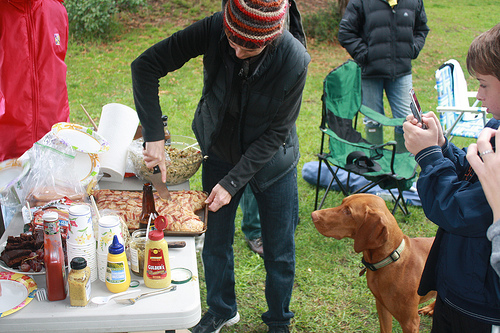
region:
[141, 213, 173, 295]
bottle of spicy mustard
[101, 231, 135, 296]
bottle of yellow mustard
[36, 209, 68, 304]
tall bottle of ketchup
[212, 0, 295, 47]
red white brown gray beanie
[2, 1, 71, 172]
red jacket with white logo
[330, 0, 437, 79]
black thermal winter jacket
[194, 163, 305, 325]
dark blue denim pants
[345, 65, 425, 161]
light blue denim pants with hole in knee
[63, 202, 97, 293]
stack of paper cups on table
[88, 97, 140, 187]
role of white paper towels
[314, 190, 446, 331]
A brown dog standing in the grass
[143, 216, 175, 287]
An open bottle of mustard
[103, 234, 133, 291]
A yellow bottle with a blue lid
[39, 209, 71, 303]
A bottle of ketchup with a white lid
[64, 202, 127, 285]
Stacks of paper cups on the table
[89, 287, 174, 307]
Plastic spoons on the table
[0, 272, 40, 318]
A white paper plate with a colorful rim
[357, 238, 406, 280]
A collar on the dog's neck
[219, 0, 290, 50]
A striped hat on the person's head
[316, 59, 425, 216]
A green canvas chair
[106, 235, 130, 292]
a bottle of mustard on a table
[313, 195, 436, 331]
a brown dog standing on the grass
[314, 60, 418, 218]
a green folding chair on the grass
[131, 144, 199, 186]
a glass bowl containing a pasta salad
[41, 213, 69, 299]
a bottle of ketchup on a table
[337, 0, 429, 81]
man with his hands in his coat pockets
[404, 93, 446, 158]
a boy holding a cell phone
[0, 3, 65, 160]
person wearing a red windbreaker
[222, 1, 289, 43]
a colorful woolen hat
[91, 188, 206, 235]
a square pizza on a metal tray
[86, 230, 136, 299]
A small jar of mustard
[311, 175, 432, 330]
A brown hound dog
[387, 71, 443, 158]
Holding a cellphone to take a photo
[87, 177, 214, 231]
A large cheese pizza in a square pan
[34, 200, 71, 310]
A Hunts Ketchup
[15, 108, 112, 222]
A pile of paper plates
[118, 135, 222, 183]
A bowl of mixed salad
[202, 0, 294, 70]
A person with a wool stripe cap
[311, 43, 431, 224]
A green outdoor chair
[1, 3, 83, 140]
A red jacket worn by a person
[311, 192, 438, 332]
brown dog wearing collar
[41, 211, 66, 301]
bottle of red ketchup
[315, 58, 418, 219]
green and black camp chair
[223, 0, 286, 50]
striped knit hat being worn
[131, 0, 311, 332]
person using knife to cut food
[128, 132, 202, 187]
large see through bowl of food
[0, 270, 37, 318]
white plate with bright colored border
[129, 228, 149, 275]
open jar of pickles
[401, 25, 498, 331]
young boy looking at phone